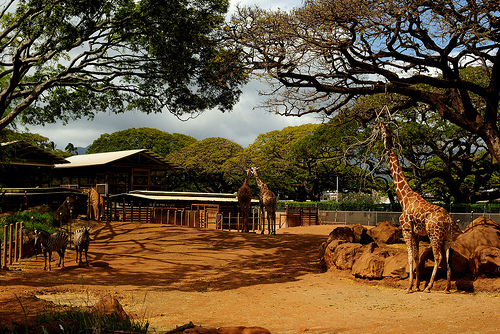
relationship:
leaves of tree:
[221, 120, 385, 222] [238, 125, 306, 177]